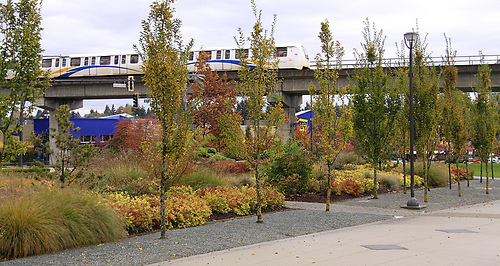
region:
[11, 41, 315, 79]
long white train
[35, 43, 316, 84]
long white train with blue design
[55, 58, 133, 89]
blue line on side of train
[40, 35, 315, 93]
train on top of tracks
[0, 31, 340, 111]
train on top of bridge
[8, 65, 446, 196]
concrete train bridge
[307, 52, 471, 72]
guard rail on side of bridge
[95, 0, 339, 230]
small trees on side walk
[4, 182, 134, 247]
bushes growing next to side walk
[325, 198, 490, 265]
concrete side walk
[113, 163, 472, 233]
a garden yellowing in autumn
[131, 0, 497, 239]
a line of young trees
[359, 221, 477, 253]
square manholes in sidewalk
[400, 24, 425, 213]
a tall lightpost with domed base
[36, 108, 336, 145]
the blue front of Best Buy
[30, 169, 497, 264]
graveled area between walk and garden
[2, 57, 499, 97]
a railway bridge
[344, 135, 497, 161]
parking area barely seen through trees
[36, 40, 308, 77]
a passenger train passing overhead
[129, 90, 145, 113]
traffic light hanging near bridge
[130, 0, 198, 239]
a small green tree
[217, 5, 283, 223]
a small green tree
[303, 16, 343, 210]
a small green tree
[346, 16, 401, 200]
a small green tree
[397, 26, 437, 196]
a small green tree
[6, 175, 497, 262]
a grey paved sidewalk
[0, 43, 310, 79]
a white and blue monorail train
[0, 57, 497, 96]
an elevated monorail track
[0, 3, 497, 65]
a cloudy blue sky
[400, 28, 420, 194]
a black street light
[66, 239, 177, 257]
falling leaves on the sidewalk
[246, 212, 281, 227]
tree trunk in the side walk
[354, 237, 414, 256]
gray square on the side walk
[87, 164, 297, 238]
garden of beautiful flowers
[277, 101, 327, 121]
white roof on blue building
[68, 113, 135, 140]
blue color on building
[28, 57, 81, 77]
yellow stripes on train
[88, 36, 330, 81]
large white passenger train on track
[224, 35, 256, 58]
window on white train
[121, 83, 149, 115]
yellow and black traffic light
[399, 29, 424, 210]
Tall black lamp post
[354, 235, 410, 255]
Decorative square paver in sidewalk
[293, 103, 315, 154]
Department store entrance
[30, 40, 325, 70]
Passenger train taking passengers to their destination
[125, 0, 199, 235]
Decorative tree along sidewalk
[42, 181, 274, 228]
Decorative landscaping in park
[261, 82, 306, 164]
Concrete bridge support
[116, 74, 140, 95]
Highway traffic control signal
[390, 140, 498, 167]
Department store parking lot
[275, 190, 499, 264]
Pedestrian walking path